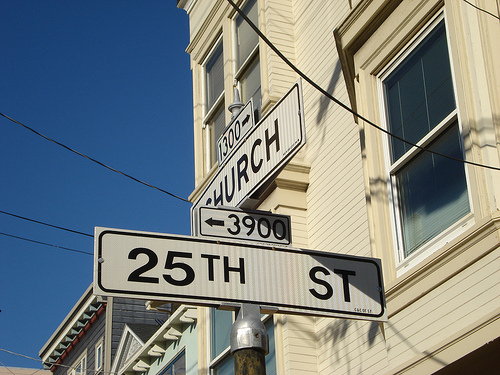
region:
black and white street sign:
[96, 228, 389, 324]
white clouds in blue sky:
[15, 20, 65, 46]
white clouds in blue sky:
[35, 145, 102, 181]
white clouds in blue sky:
[25, 225, 65, 265]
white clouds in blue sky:
[20, 275, 50, 300]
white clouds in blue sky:
[70, 50, 101, 76]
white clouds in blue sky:
[80, 41, 115, 81]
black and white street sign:
[201, 100, 261, 157]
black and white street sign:
[185, 104, 311, 190]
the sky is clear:
[26, 75, 136, 195]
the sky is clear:
[54, 58, 181, 173]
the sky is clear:
[83, 80, 157, 149]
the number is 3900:
[187, 200, 312, 255]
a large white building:
[175, 0, 499, 374]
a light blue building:
[107, 303, 197, 373]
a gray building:
[37, 280, 169, 373]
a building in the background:
[0, 365, 53, 374]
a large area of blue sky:
[0, 0, 195, 369]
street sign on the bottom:
[93, 225, 388, 321]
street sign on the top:
[190, 75, 307, 235]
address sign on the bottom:
[196, 203, 291, 248]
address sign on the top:
[216, 97, 255, 169]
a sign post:
[231, 348, 266, 374]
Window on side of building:
[375, 5, 477, 279]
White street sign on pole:
[86, 223, 389, 322]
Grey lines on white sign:
[259, 245, 301, 302]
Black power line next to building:
[1, 108, 189, 212]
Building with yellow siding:
[183, 7, 498, 374]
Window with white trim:
[376, 5, 476, 280]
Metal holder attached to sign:
[213, 300, 280, 352]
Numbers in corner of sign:
[353, 305, 372, 313]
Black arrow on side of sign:
[203, 215, 225, 227]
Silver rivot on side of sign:
[95, 255, 105, 265]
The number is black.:
[226, 213, 242, 238]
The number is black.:
[241, 215, 258, 240]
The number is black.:
[256, 210, 273, 240]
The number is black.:
[269, 215, 289, 243]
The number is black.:
[121, 239, 164, 289]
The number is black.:
[161, 244, 200, 286]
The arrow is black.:
[203, 211, 228, 233]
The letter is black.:
[195, 248, 222, 288]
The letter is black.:
[220, 252, 251, 287]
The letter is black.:
[302, 259, 335, 304]